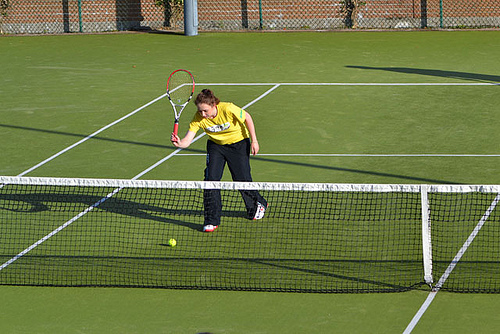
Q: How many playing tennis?
A: One.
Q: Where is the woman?
A: In the tennis court.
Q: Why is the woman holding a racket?
A: To play.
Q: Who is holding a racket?
A: A woman.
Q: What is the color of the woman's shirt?
A: Yellow.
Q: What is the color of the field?
A: Green.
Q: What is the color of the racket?
A: Red and white.